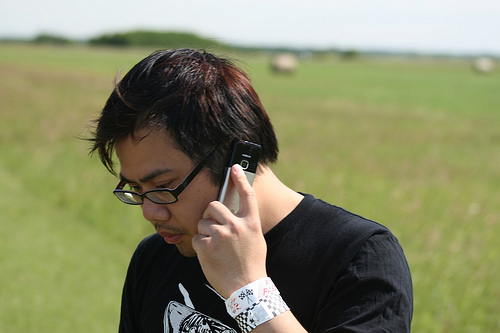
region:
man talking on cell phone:
[77, 47, 413, 332]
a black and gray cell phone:
[217, 140, 260, 214]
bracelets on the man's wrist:
[226, 275, 288, 331]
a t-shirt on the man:
[115, 190, 414, 331]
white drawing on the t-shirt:
[161, 283, 239, 332]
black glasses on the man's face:
[113, 142, 224, 204]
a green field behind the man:
[0, 43, 499, 331]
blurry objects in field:
[266, 53, 494, 75]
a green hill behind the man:
[40, 27, 231, 49]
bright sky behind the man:
[1, 0, 498, 54]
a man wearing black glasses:
[111, 160, 220, 204]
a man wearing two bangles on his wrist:
[223, 275, 288, 329]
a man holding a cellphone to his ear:
[197, 135, 270, 310]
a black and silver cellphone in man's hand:
[198, 140, 268, 301]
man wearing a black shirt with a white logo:
[118, 198, 412, 332]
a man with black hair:
[78, 48, 280, 258]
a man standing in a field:
[73, 41, 445, 331]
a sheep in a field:
[268, 50, 299, 76]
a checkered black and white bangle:
[236, 293, 301, 332]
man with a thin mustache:
[152, 218, 189, 237]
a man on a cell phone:
[8, 34, 378, 285]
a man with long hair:
[30, 20, 469, 309]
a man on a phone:
[17, 27, 407, 330]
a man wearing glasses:
[50, 41, 420, 331]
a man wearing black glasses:
[51, 56, 342, 331]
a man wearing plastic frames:
[44, 32, 418, 329]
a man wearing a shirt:
[39, 59, 421, 329]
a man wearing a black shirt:
[37, 20, 426, 330]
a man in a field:
[73, 21, 453, 331]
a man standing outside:
[39, 38, 429, 330]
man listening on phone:
[73, 46, 415, 331]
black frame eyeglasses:
[110, 170, 205, 206]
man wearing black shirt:
[76, 41, 417, 331]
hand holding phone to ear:
[189, 139, 281, 291]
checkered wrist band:
[229, 301, 299, 330]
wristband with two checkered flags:
[220, 277, 275, 310]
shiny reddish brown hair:
[78, 43, 280, 173]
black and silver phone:
[220, 134, 262, 216]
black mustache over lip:
[152, 221, 192, 236]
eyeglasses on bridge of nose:
[110, 167, 205, 223]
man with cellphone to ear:
[66, 40, 416, 327]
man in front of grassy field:
[22, 16, 487, 321]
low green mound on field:
[27, 25, 237, 55]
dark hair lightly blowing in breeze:
[70, 40, 281, 180]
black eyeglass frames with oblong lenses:
[110, 155, 205, 205]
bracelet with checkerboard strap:
[225, 295, 295, 330]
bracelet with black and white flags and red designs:
[222, 275, 278, 311]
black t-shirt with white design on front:
[117, 190, 412, 326]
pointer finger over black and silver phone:
[220, 126, 260, 218]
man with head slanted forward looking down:
[113, 147, 195, 253]